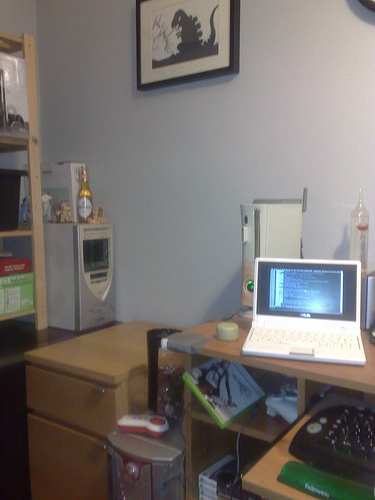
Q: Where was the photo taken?
A: In a room.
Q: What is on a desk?
A: Laptop computer.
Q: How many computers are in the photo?
A: One.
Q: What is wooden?
A: The desk.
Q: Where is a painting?
A: On the wall.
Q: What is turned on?
A: Computer.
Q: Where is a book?
A: On a shelf.